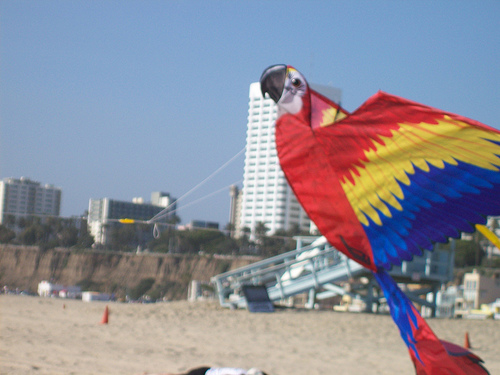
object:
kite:
[256, 61, 500, 373]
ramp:
[208, 240, 374, 314]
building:
[236, 80, 345, 248]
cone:
[102, 306, 111, 324]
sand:
[1, 296, 498, 374]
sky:
[1, 1, 498, 224]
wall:
[476, 275, 495, 319]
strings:
[143, 124, 277, 219]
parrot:
[259, 64, 497, 374]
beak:
[256, 64, 289, 98]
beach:
[0, 293, 500, 375]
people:
[226, 287, 242, 310]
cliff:
[2, 244, 277, 306]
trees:
[74, 222, 95, 253]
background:
[0, 0, 500, 374]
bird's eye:
[293, 78, 301, 86]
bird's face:
[260, 65, 306, 106]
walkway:
[211, 233, 381, 308]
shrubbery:
[7, 222, 293, 256]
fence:
[0, 238, 271, 264]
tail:
[375, 272, 489, 374]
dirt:
[0, 298, 497, 374]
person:
[186, 364, 268, 373]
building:
[85, 187, 179, 251]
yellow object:
[120, 217, 135, 224]